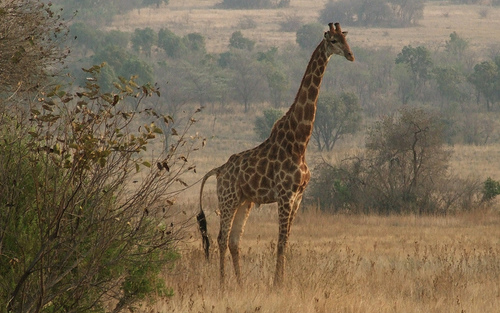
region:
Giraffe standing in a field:
[156, 17, 372, 280]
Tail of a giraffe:
[186, 143, 228, 265]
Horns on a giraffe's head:
[321, 17, 346, 34]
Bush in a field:
[40, 66, 194, 283]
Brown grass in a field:
[331, 233, 432, 300]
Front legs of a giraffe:
[270, 194, 304, 280]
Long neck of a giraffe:
[295, 36, 332, 139]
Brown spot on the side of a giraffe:
[253, 156, 272, 182]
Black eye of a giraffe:
[328, 38, 342, 50]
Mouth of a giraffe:
[342, 51, 357, 64]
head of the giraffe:
[306, 16, 372, 73]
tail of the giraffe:
[175, 175, 215, 255]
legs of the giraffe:
[195, 200, 315, 295]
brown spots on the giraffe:
[225, 145, 285, 200]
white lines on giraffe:
[225, 155, 285, 195]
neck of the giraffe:
[272, 60, 347, 125]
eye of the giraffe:
[324, 32, 344, 52]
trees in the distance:
[127, 23, 267, 128]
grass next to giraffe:
[326, 240, 398, 305]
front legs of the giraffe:
[260, 185, 326, 302]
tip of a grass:
[345, 280, 357, 291]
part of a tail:
[206, 229, 216, 236]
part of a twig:
[112, 225, 132, 283]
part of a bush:
[161, 264, 178, 274]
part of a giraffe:
[244, 173, 254, 183]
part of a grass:
[366, 275, 385, 294]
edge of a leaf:
[123, 115, 140, 129]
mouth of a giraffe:
[348, 48, 353, 59]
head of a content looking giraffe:
[316, 18, 356, 65]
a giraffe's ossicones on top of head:
[325, 15, 346, 39]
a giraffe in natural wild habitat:
[196, 16, 358, 299]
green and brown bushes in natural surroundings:
[1, 2, 206, 312]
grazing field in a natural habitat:
[100, 190, 498, 311]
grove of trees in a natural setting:
[3, 1, 498, 216]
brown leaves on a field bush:
[4, 1, 203, 308]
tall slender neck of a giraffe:
[266, 39, 334, 148]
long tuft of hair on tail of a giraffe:
[191, 202, 219, 264]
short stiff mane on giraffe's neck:
[273, 37, 335, 119]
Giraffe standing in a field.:
[180, 17, 371, 307]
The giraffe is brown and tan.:
[186, 20, 356, 300]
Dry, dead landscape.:
[0, 1, 495, 308]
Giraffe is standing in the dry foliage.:
[188, 16, 356, 309]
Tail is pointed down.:
[191, 162, 226, 264]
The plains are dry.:
[0, 214, 496, 312]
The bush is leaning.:
[3, 2, 209, 312]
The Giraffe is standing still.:
[185, 19, 360, 304]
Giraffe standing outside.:
[188, 14, 362, 308]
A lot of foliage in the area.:
[3, 2, 498, 312]